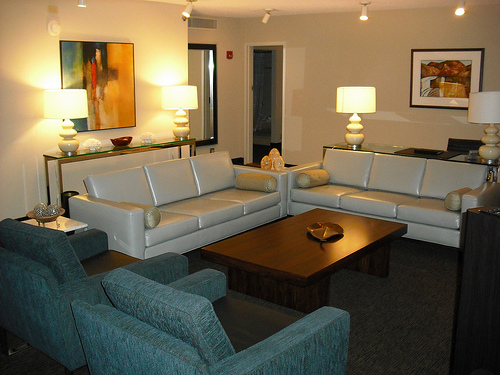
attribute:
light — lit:
[359, 2, 368, 19]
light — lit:
[453, 0, 465, 19]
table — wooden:
[198, 179, 418, 289]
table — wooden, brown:
[200, 207, 408, 312]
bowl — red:
[107, 132, 135, 150]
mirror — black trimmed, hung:
[184, 40, 220, 147]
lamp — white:
[468, 87, 498, 167]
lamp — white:
[337, 86, 377, 147]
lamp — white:
[165, 87, 197, 134]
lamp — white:
[39, 88, 89, 153]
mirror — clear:
[187, 43, 219, 147]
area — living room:
[77, 42, 424, 290]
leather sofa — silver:
[61, 147, 289, 258]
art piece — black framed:
[419, 57, 471, 102]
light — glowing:
[41, 82, 92, 124]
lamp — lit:
[327, 76, 395, 161]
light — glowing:
[256, 1, 281, 26]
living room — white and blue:
[3, 2, 495, 373]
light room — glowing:
[297, 70, 394, 151]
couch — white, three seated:
[282, 145, 494, 252]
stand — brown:
[51, 139, 194, 158]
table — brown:
[246, 153, 312, 175]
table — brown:
[0, 206, 87, 239]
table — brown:
[43, 131, 215, 168]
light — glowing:
[306, 57, 412, 164]